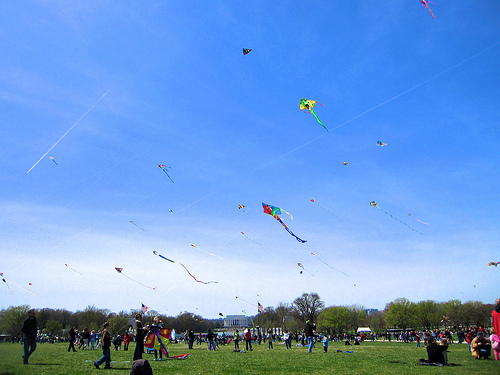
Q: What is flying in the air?
A: Kites.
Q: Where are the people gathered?
A: Park.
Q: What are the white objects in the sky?
A: Clouds.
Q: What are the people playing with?
A: Kites.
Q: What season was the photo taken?
A: Summer.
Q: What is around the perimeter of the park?
A: Trees.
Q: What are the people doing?
A: Flying kites.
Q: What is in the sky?
A: Kites.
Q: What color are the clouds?
A: White.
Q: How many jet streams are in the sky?
A: 2.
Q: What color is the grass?
A: Green.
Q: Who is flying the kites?
A: People.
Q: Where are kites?
A: In the sky.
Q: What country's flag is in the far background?
A: USA.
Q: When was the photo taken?
A: Daytime.